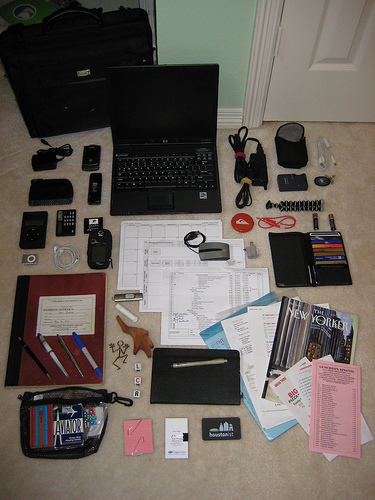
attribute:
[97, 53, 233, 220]
laptop — open, black, off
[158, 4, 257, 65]
wall — green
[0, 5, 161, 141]
bag — black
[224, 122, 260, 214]
cord — power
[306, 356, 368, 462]
page — pink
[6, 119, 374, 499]
floor — various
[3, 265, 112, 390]
notebook — red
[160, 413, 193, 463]
card — white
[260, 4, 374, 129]
door — white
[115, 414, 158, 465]
card — pink